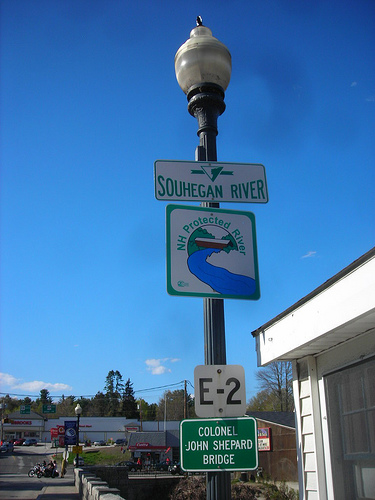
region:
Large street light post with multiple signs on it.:
[152, 6, 275, 488]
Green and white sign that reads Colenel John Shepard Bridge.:
[178, 417, 257, 473]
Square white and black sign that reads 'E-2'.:
[194, 361, 245, 415]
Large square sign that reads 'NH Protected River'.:
[167, 208, 253, 294]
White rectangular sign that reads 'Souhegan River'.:
[155, 157, 270, 203]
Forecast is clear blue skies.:
[4, 94, 159, 374]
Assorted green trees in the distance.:
[2, 387, 187, 415]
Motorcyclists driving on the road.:
[27, 457, 58, 482]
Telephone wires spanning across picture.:
[2, 382, 193, 399]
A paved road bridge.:
[10, 468, 123, 498]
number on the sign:
[221, 377, 241, 405]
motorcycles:
[25, 461, 49, 474]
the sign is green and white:
[177, 422, 257, 470]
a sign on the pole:
[169, 205, 257, 296]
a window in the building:
[328, 377, 372, 452]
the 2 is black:
[223, 377, 242, 408]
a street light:
[73, 401, 80, 413]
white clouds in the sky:
[143, 353, 179, 378]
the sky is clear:
[9, 249, 129, 326]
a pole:
[201, 301, 233, 363]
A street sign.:
[199, 415, 261, 472]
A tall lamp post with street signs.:
[154, 15, 265, 497]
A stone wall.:
[67, 465, 107, 498]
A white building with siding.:
[253, 319, 371, 493]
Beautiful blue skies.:
[36, 232, 115, 258]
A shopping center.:
[0, 413, 180, 440]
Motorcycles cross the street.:
[30, 454, 63, 477]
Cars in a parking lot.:
[1, 437, 35, 449]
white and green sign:
[156, 146, 273, 214]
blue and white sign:
[163, 211, 263, 311]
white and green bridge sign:
[172, 410, 255, 468]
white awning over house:
[252, 265, 373, 361]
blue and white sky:
[1, 286, 188, 402]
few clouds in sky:
[4, 343, 161, 395]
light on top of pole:
[165, 11, 232, 105]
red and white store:
[16, 404, 176, 451]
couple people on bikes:
[21, 461, 70, 484]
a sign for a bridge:
[170, 415, 288, 476]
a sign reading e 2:
[177, 363, 263, 416]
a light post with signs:
[144, 25, 281, 453]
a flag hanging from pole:
[62, 397, 86, 474]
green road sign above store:
[18, 397, 58, 423]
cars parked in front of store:
[5, 435, 46, 458]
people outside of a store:
[127, 450, 179, 468]